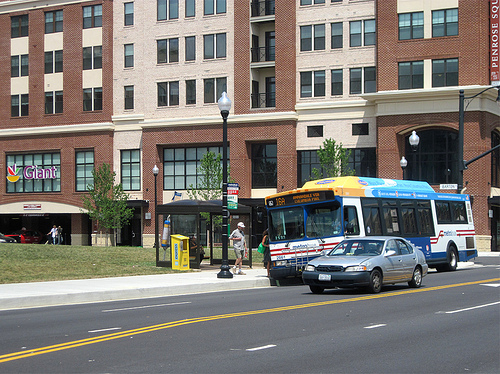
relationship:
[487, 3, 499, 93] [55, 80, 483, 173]
sign on side of a building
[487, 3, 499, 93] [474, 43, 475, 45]
sign with text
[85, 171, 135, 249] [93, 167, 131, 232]
tree has green leaves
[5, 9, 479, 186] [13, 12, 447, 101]
building has windows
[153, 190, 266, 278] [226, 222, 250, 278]
bus stop has a man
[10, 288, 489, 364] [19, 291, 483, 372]
street has lines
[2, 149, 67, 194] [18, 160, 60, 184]
window reads giant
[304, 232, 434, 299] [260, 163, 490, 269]
car driving next to bus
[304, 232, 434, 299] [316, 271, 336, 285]
car has license plate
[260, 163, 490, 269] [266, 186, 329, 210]
bus has marquee display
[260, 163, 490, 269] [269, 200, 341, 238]
bus has front windows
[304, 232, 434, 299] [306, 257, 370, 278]
car has headlights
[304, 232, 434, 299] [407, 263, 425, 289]
car has back tire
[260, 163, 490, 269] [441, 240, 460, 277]
bus has back tire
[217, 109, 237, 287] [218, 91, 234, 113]
post has light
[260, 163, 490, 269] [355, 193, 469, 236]
bus has passenger windows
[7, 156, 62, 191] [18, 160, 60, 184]
sign says giant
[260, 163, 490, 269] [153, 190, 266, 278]
bus has stop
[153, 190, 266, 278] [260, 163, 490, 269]
bus stop has a bus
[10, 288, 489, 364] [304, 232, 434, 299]
road has a car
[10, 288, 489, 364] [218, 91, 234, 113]
street has light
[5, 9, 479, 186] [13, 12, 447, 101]
building has a lot of windows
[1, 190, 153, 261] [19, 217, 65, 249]
background has people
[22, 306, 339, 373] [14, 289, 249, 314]
road has a side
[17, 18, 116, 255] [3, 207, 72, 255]
building has an entrance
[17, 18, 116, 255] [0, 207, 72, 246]
building has entrance